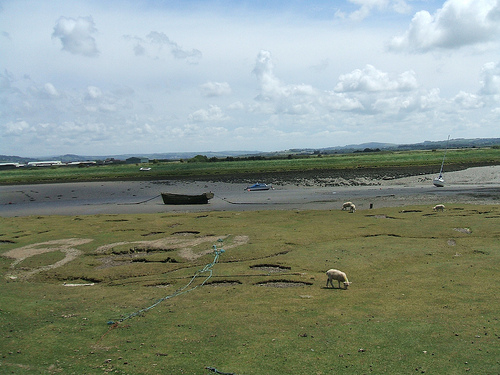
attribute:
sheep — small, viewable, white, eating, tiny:
[323, 264, 358, 298]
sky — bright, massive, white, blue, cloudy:
[3, 1, 500, 146]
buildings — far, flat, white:
[3, 156, 103, 169]